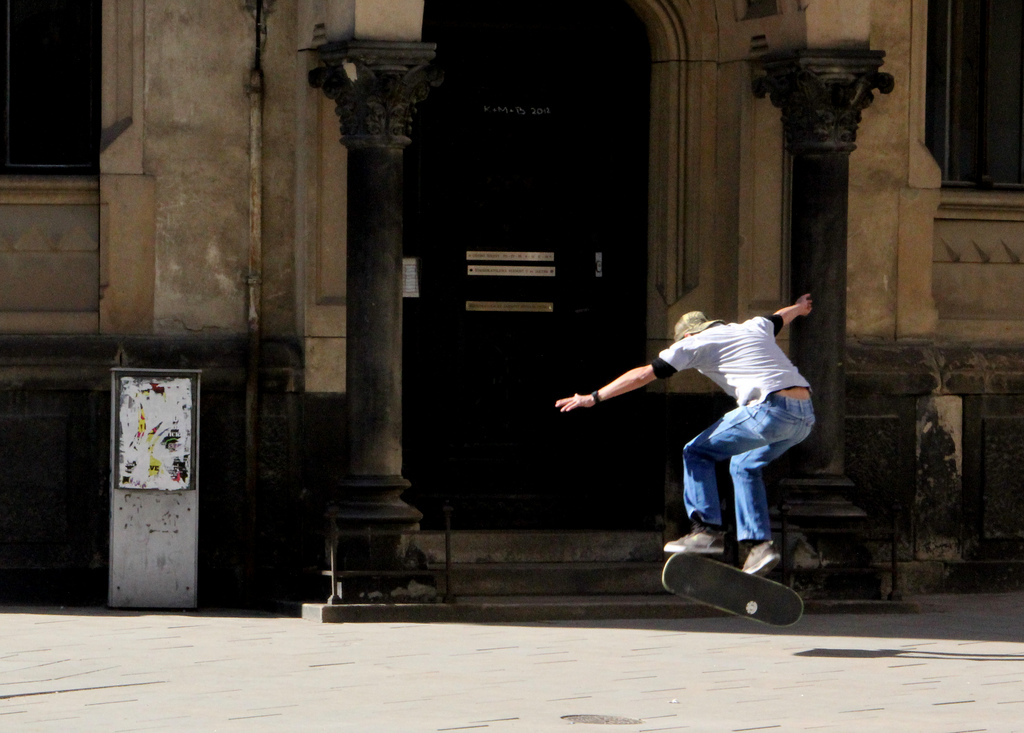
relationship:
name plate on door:
[464, 298, 551, 315] [402, 1, 650, 530]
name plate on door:
[466, 266, 553, 277] [402, 1, 650, 530]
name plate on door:
[466, 250, 552, 266] [402, 1, 650, 530]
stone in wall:
[858, 182, 902, 306] [1, 1, 267, 330]